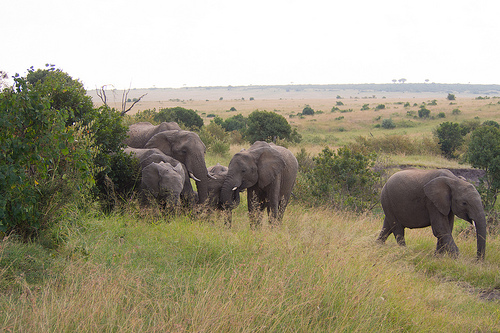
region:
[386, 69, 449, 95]
Trees in the distant horizon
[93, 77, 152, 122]
Tree with no leaves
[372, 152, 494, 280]
Elephant walking alone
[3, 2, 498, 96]
Clear distant white skky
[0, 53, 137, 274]
Large bushes on the left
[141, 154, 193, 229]
Elephant head pointed toward ground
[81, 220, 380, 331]
Thick green and beige grass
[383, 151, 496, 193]
Little patch of brown earth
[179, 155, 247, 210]
Two elephant trunks with white tusks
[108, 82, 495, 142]
Vast plains behind elephants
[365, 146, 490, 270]
An elephant walks through the tall grass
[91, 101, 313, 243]
A group of elephants gathers in the grass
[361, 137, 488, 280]
The elephant has white tusks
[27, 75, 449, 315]
There are small trees throughout the grassland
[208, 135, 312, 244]
The elephant touches the smaller elephant with its trunk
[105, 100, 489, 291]
There are six elephants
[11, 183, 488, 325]
The tall grass is brown and light green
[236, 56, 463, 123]
The sky is clear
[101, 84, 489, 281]
The elephants are grey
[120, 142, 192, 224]
The smaller elephant stands in the grass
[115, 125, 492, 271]
Elephants are walking.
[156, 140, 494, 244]
Elephants are grey color.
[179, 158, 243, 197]
Tusks are white color.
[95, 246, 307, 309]
Grass are brown and green color.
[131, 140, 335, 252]
Elephants are in grass.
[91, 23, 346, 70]
Sky is white color.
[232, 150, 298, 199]
Elephants have two big ears.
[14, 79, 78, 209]
Bushes are green color.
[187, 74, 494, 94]
Small foot hill is seen behind the elephant.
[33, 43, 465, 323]
Day time picture.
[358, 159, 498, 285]
baby elephant walking across grass.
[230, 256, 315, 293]
patch of grass in a field.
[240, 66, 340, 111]
section of a hill.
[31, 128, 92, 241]
bush in the middle of a field.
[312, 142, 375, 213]
wild green brush growing.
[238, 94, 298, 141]
tree in the middle of a field.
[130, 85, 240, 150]
dry grass and plant covered field.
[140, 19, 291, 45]
patch of hazy sky.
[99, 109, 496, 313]
family of elephants grazing on grass.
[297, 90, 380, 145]
wild plants growing in a field.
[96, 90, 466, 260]
the elephants are grazing.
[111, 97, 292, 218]
the elephants are brown.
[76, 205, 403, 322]
the grass is dying.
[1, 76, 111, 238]
the trees are green.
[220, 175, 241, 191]
elephant tusk is white.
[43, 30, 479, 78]
the sky is white.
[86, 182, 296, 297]
green grass is patchy.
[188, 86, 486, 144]
clusters of bushes in background.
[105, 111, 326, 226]
elephants are eating grass.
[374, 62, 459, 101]
tall trees in the background.